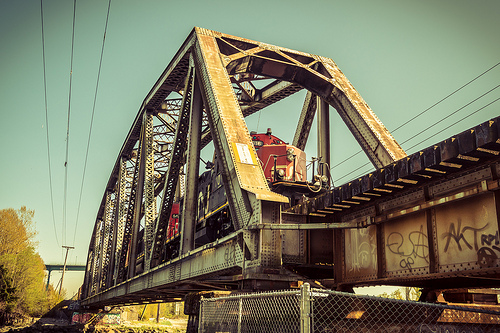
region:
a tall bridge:
[41, 47, 391, 270]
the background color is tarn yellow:
[26, 123, 394, 330]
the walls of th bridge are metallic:
[130, 133, 220, 260]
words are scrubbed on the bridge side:
[381, 227, 453, 270]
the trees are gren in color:
[3, 224, 64, 315]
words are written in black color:
[391, 222, 493, 262]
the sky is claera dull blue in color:
[420, 18, 484, 128]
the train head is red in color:
[274, 119, 344, 203]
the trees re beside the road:
[11, 221, 76, 304]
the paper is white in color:
[235, 142, 265, 178]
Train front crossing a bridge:
[241, 126, 333, 196]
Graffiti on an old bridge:
[381, 222, 493, 278]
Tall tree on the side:
[2, 201, 47, 316]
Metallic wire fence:
[245, 281, 325, 331]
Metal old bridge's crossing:
[176, 20, 411, 200]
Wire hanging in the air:
[31, 7, 111, 136]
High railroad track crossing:
[294, 117, 497, 217]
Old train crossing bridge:
[76, 26, 411, 300]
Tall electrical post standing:
[54, 242, 77, 295]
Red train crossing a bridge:
[160, 129, 327, 241]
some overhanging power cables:
[28, 0, 113, 265]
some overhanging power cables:
[331, 58, 498, 185]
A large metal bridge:
[67, 25, 499, 310]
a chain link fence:
[192, 280, 499, 330]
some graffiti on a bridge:
[348, 218, 498, 273]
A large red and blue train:
[107, 124, 331, 276]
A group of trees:
[0, 200, 56, 325]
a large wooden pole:
[56, 243, 77, 302]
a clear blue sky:
[11, 4, 498, 298]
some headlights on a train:
[274, 143, 331, 185]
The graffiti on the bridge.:
[339, 221, 497, 249]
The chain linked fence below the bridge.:
[199, 297, 497, 332]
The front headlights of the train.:
[270, 170, 307, 178]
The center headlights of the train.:
[287, 143, 297, 161]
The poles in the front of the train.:
[265, 152, 333, 189]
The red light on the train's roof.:
[266, 126, 272, 136]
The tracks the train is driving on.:
[142, 128, 496, 242]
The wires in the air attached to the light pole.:
[30, 1, 91, 247]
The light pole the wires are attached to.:
[58, 241, 75, 294]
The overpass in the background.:
[40, 255, 92, 275]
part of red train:
[246, 124, 332, 205]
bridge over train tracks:
[65, 21, 412, 311]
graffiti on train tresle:
[338, 215, 495, 280]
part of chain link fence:
[192, 288, 243, 329]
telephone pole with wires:
[50, 233, 77, 298]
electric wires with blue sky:
[27, 3, 109, 243]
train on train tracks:
[76, 111, 340, 309]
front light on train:
[272, 163, 287, 180]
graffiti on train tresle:
[440, 220, 496, 273]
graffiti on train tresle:
[382, 227, 430, 272]